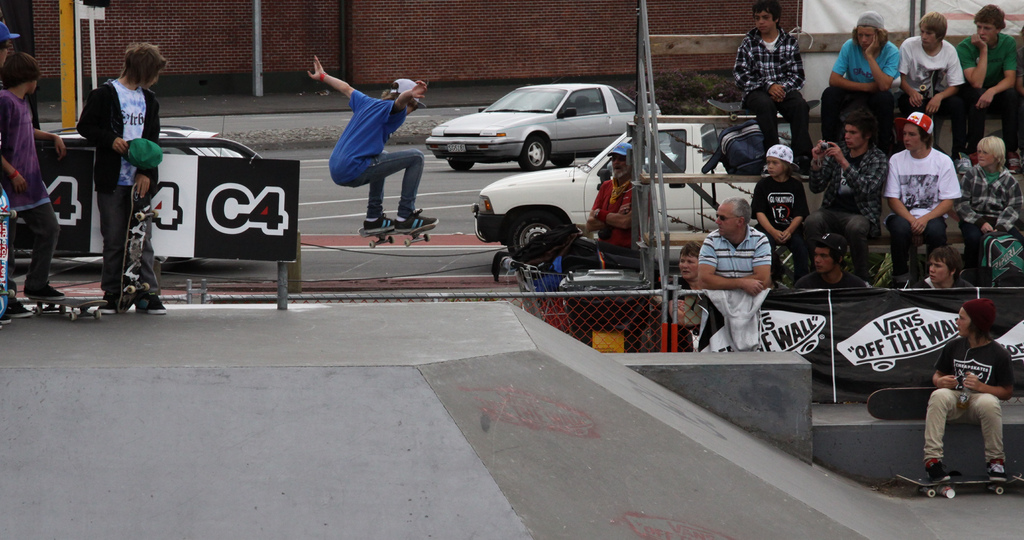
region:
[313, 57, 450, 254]
a skateboarder midair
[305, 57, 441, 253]
a skateboarder doing a trick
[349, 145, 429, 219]
a person wearing blue jeans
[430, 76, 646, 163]
a grey colored car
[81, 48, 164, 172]
a boy holding a green hat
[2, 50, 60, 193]
a boy in a purple shirt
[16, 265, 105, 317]
a foot standing on a skateboard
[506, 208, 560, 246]
the wheel of a vehicle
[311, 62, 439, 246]
a kid is skateboarding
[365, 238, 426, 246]
wheels on the board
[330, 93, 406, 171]
the shirt is blue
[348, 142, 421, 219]
the pants are gray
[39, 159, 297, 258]
black and white sign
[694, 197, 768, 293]
a man is looking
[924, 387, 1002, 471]
the pants are khaki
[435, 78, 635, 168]
car on the road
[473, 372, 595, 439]
red stain on ground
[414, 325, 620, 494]
a view of mark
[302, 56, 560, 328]
a man in air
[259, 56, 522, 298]
a man performing stunt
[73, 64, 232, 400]
a man near board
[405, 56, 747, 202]
car in the road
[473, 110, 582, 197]
tire of the car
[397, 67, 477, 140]
hand of the person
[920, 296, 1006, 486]
person sitting watching skateboarder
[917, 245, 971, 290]
person sitting watching skateboarder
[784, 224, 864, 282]
person sitting watching skateboarder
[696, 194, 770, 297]
person sitting watching skateboarder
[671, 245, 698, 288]
person sitting watching skateboarder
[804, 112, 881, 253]
person sitting watching skateboarder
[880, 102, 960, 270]
person sitting watching skateboarder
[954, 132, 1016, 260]
person sitting watching skateboarder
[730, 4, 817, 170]
person sitting watching skateboarder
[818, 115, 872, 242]
A person is sitting down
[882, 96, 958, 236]
A person is sitting down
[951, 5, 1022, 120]
A person is sitting down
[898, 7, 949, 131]
A person is sitting down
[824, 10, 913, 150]
A person is sitting down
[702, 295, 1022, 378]
Advertising signs for Vans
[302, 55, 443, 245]
Skateboarder in the air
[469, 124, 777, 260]
white truck parked on the side of the road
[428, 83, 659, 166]
Silver car in the road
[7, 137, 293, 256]
Signs saying C4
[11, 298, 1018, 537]
Grey skateboard ramp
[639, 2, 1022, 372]
Bleachers for people to sit on and watch skateboarders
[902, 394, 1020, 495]
skater has his feet on the skateboard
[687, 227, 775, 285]
man's shirt has stripes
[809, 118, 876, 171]
guy is taking a picture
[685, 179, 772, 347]
A person is sitting down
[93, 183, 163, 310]
the mans legs below torso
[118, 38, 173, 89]
the mans head above shoulders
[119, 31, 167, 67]
the hair on the mans head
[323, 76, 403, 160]
the mans shirt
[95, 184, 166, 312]
the mans pants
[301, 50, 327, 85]
the mans hand at end of arm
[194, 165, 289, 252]
black part of sign that says c4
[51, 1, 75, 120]
yellow pole in back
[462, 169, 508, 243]
front of white truck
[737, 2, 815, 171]
person watching skateboard event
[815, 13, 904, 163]
person watching skateboard event